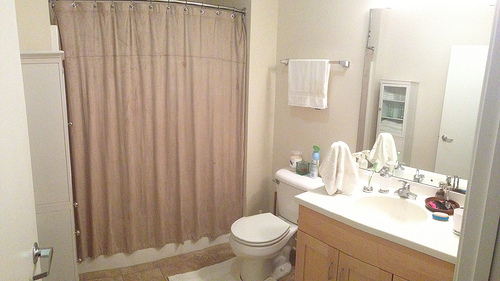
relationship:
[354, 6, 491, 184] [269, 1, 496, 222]
mirror on wall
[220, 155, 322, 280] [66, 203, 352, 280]
toilet on floor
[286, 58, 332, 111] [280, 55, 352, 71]
towel hanging on rack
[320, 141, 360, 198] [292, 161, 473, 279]
towel sitting on sink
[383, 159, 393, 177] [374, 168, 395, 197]
tooth brush in cup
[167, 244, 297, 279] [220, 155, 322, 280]
mat underneath toilet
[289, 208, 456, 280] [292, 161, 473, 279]
cabinet under sink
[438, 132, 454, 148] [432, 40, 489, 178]
knob on door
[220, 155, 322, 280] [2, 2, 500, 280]
toilet in bathroom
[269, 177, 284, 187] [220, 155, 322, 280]
handle on toilet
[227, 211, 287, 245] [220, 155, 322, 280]
seat on toilet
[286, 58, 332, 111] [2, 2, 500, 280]
towel in bathroom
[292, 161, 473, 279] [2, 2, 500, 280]
sink in bathroom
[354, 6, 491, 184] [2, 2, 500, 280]
mirror in bathroom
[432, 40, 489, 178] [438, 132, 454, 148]
door has knob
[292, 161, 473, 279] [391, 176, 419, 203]
sink has faucet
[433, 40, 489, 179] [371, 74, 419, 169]
door of storage cabinet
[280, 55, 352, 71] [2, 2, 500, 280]
rack in bathroom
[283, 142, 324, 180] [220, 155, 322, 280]
bottles on back of toilet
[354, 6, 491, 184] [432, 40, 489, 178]
mirror reflecting door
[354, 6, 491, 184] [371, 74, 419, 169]
mirror reflecting storage cabinet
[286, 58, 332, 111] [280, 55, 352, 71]
towel hanging from rack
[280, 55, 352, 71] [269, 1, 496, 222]
rack on wall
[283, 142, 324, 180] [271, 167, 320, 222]
bottles on toilet tank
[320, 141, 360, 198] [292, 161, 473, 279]
towel on sink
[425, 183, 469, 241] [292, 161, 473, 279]
containers next to sink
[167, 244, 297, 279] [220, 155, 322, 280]
mat surrounding base of toilet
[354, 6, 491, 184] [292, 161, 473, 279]
mirror above sink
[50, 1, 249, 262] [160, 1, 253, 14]
shower curtain hanging on bar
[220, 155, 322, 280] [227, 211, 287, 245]
toilet has seat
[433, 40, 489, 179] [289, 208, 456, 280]
door of cabinet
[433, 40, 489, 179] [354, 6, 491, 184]
door on mirror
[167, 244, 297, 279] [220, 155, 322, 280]
mat around toilet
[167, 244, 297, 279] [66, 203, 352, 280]
mat on floor